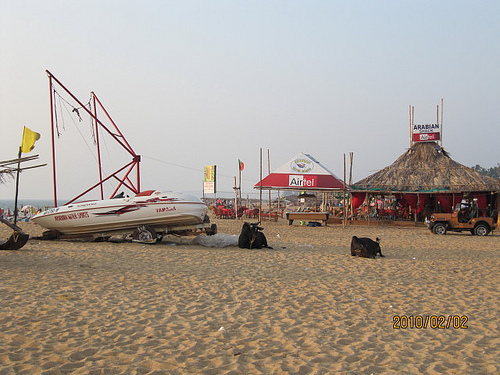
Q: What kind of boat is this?
A: Motor.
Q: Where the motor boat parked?
A: On the sand.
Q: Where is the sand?
A: All over the place.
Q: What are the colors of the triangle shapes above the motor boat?
A: Red.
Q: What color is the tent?
A: Red.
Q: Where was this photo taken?
A: The beach.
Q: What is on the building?
A: A roof.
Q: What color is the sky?
A: Blue.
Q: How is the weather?
A: It is clear.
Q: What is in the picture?
A: A boat and jeep.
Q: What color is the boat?
A: White.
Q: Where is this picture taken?
A: The beach.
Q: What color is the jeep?
A: Orange.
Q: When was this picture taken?
A: Daytime.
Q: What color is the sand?
A: Brown.